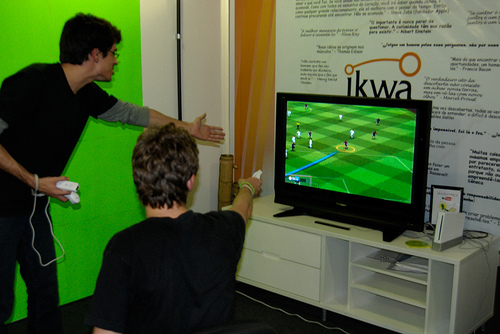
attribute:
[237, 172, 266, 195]
wristband — green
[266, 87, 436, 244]
tv — on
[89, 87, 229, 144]
arm — stretched out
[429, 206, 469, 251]
console — white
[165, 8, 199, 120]
cord — black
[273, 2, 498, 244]
wall — white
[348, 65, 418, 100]
letters — black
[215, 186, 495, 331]
tv stand — white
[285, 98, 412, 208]
television — on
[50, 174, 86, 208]
game — white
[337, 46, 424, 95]
logo — orange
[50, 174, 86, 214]
controllers — white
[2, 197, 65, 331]
pants — black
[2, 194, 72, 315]
pants — black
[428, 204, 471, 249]
console — Wii